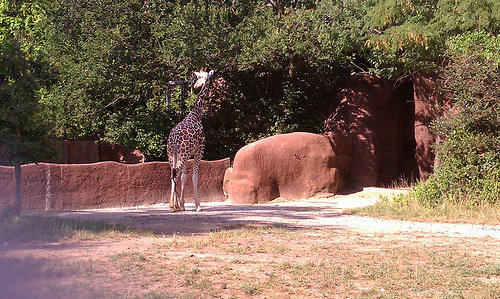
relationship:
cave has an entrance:
[339, 60, 468, 196] [382, 77, 415, 188]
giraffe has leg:
[166, 68, 214, 212] [192, 153, 203, 212]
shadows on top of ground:
[7, 205, 326, 245] [3, 204, 497, 294]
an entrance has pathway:
[370, 73, 422, 188] [249, 185, 408, 234]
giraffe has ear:
[166, 68, 214, 212] [209, 69, 216, 76]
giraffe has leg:
[166, 68, 214, 212] [179, 157, 187, 211]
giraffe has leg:
[166, 68, 214, 212] [167, 156, 181, 213]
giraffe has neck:
[166, 68, 214, 212] [192, 79, 212, 120]